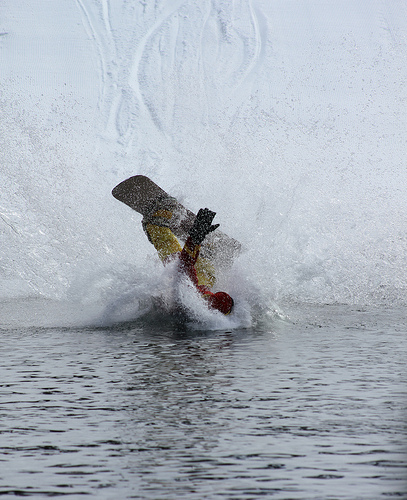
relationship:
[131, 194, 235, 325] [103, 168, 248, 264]
man on board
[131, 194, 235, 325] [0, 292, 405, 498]
man falling in water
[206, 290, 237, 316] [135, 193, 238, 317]
head of person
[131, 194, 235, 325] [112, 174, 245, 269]
man on snowboard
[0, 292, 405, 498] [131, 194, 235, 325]
water in front of man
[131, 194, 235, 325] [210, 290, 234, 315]
man with hat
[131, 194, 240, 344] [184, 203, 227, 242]
man with gloves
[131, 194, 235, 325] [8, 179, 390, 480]
man in water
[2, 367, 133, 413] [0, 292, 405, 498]
ripples in water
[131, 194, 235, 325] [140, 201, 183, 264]
man wearing yellow pants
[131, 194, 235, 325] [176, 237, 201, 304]
man wearing sleeve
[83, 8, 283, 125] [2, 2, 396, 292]
tracks on snow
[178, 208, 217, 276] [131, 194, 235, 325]
arm on man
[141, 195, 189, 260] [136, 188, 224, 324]
leg on person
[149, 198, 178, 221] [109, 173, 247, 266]
feet on board